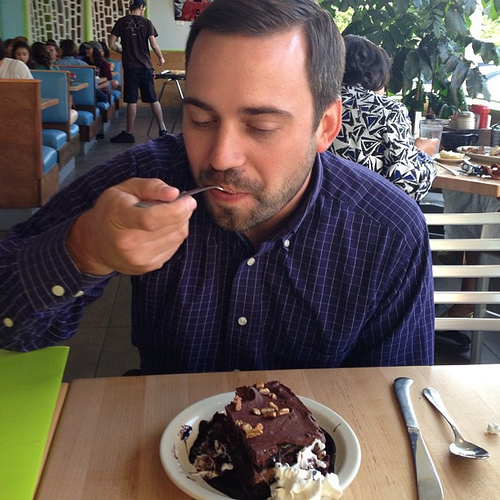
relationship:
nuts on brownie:
[252, 401, 291, 419] [218, 375, 326, 463]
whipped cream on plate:
[289, 469, 329, 485] [163, 393, 214, 419]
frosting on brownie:
[224, 434, 273, 461] [218, 375, 326, 463]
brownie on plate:
[218, 375, 326, 463] [163, 393, 214, 419]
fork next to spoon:
[188, 184, 240, 206] [422, 367, 479, 470]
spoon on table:
[422, 367, 479, 470] [56, 388, 127, 424]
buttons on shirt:
[235, 256, 264, 268] [149, 262, 397, 349]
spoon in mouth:
[422, 367, 479, 470] [188, 169, 256, 210]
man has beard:
[40, 0, 430, 355] [207, 220, 271, 229]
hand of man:
[79, 166, 167, 298] [40, 0, 430, 355]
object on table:
[1, 382, 84, 420] [56, 388, 127, 424]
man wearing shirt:
[40, 0, 430, 355] [149, 262, 397, 349]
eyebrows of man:
[180, 89, 288, 121] [40, 0, 430, 355]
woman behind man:
[336, 24, 420, 177] [40, 0, 430, 355]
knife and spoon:
[386, 387, 439, 497] [422, 367, 479, 470]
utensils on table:
[396, 376, 484, 490] [56, 388, 127, 424]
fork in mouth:
[188, 184, 240, 206] [188, 169, 256, 210]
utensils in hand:
[396, 376, 484, 490] [79, 166, 167, 298]